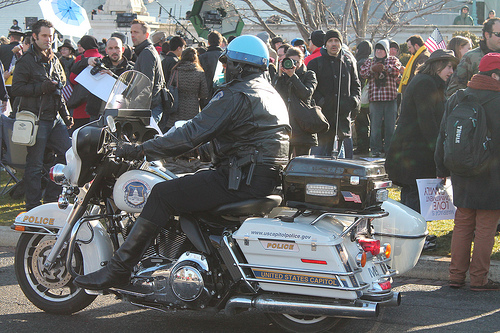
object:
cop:
[72, 32, 295, 289]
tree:
[344, 0, 473, 52]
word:
[21, 215, 55, 225]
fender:
[11, 199, 114, 296]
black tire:
[11, 224, 103, 316]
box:
[277, 152, 393, 214]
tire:
[12, 227, 103, 316]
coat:
[358, 54, 406, 104]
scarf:
[396, 44, 426, 94]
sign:
[411, 175, 459, 223]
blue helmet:
[217, 34, 271, 71]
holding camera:
[278, 57, 297, 72]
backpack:
[440, 94, 495, 177]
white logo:
[453, 121, 462, 145]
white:
[254, 251, 301, 269]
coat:
[140, 73, 294, 182]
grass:
[422, 224, 454, 256]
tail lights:
[381, 242, 393, 258]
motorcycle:
[8, 70, 435, 332]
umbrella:
[39, 0, 91, 40]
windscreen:
[104, 70, 156, 112]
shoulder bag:
[11, 97, 44, 147]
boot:
[70, 216, 162, 291]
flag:
[340, 189, 363, 203]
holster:
[226, 151, 258, 192]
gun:
[225, 150, 259, 192]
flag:
[423, 23, 447, 54]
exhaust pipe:
[228, 292, 381, 321]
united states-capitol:
[246, 267, 344, 289]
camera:
[279, 57, 296, 68]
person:
[381, 48, 462, 253]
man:
[70, 33, 295, 294]